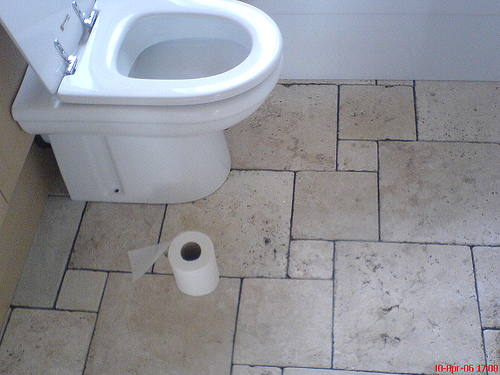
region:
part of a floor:
[311, 194, 358, 232]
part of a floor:
[358, 306, 378, 332]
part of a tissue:
[196, 280, 210, 293]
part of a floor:
[333, 251, 360, 289]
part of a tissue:
[114, 248, 174, 371]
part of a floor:
[268, 290, 304, 337]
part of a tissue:
[149, 218, 202, 343]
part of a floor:
[342, 300, 382, 371]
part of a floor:
[346, 287, 373, 323]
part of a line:
[318, 280, 353, 322]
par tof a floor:
[319, 259, 342, 302]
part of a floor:
[328, 268, 366, 327]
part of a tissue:
[126, 240, 153, 343]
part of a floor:
[364, 269, 403, 307]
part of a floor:
[315, 278, 352, 330]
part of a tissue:
[108, 201, 196, 341]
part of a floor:
[321, 257, 347, 304]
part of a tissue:
[180, 253, 190, 272]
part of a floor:
[324, 235, 373, 291]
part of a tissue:
[183, 253, 202, 280]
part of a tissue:
[183, 256, 213, 316]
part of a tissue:
[182, 246, 217, 295]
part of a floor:
[352, 260, 387, 303]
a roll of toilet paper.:
[120, 225, 222, 320]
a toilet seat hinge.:
[55, 23, 79, 77]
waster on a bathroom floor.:
[257, 229, 282, 265]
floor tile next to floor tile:
[11, 194, 92, 309]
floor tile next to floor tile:
[65, 201, 166, 271]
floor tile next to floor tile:
[153, 170, 295, 276]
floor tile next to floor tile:
[292, 171, 381, 241]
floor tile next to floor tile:
[338, 141, 378, 171]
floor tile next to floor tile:
[287, 240, 335, 281]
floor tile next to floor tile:
[233, 278, 333, 367]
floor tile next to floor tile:
[332, 241, 485, 372]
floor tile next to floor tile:
[470, 244, 495, 325]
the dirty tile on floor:
[0, 79, 499, 370]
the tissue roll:
[122, 224, 225, 302]